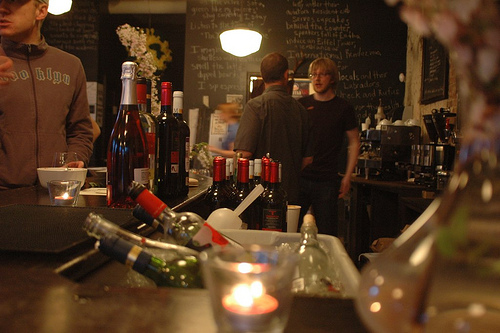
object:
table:
[5, 159, 215, 263]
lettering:
[2, 66, 16, 82]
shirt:
[283, 88, 354, 198]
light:
[216, 26, 264, 55]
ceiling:
[140, 1, 388, 16]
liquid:
[100, 156, 151, 208]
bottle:
[110, 63, 154, 208]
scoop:
[207, 183, 267, 231]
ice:
[197, 212, 341, 301]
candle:
[226, 277, 278, 331]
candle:
[46, 183, 81, 205]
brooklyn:
[4, 64, 72, 86]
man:
[233, 40, 309, 230]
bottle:
[89, 217, 208, 298]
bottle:
[132, 182, 239, 260]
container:
[146, 215, 376, 301]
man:
[296, 60, 368, 247]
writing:
[194, 84, 213, 91]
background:
[132, 99, 468, 196]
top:
[100, 100, 174, 143]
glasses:
[307, 70, 329, 75]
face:
[305, 49, 330, 94]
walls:
[308, 13, 376, 52]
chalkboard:
[285, 7, 356, 38]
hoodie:
[0, 35, 97, 193]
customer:
[2, 1, 98, 190]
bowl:
[34, 162, 88, 191]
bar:
[8, 162, 368, 325]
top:
[114, 55, 144, 103]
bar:
[2, 159, 481, 325]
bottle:
[94, 228, 208, 284]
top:
[80, 236, 150, 266]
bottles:
[261, 160, 282, 226]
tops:
[277, 158, 284, 184]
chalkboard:
[185, 35, 247, 115]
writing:
[217, 71, 226, 80]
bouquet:
[111, 21, 173, 114]